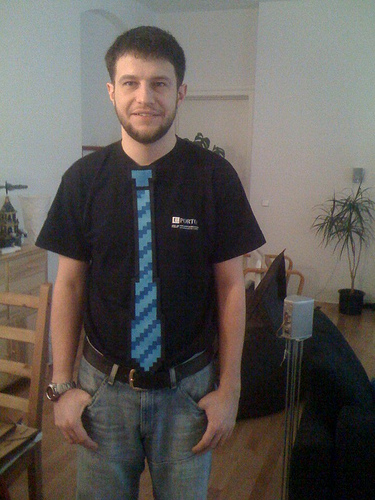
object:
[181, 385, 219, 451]
pocket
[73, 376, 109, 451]
pocket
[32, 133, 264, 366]
t-shirt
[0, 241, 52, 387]
chest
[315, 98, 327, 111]
ground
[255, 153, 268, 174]
ground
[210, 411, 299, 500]
floors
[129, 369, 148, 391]
clip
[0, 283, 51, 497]
light wood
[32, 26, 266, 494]
man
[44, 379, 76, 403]
wristwatch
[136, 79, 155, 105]
nose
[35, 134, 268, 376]
black t-shirt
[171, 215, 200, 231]
logo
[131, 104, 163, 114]
moustache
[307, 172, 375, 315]
houseplant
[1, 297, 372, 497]
wooden floor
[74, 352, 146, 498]
leg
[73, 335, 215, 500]
jeans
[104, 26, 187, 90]
hair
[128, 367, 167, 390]
buckle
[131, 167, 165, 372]
tie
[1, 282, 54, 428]
shelf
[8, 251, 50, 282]
drawer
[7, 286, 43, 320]
drawer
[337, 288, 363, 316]
pot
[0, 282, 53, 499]
chair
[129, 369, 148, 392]
hinge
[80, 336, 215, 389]
belt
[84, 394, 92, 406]
thumb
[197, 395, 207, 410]
thumb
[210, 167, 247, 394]
arm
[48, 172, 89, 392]
arm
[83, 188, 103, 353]
side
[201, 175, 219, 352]
side